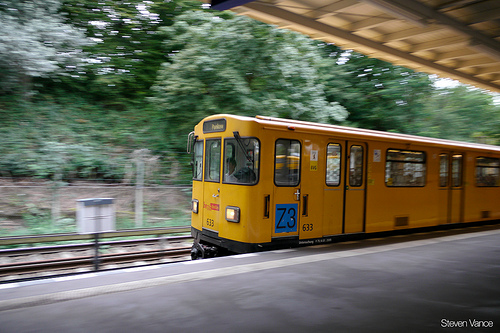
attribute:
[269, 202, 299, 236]
z3 — blue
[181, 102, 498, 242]
train — yellow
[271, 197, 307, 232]
square — blue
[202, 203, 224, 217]
red — painted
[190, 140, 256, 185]
windows — three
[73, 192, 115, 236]
sign — white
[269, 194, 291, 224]
notation — black, blue